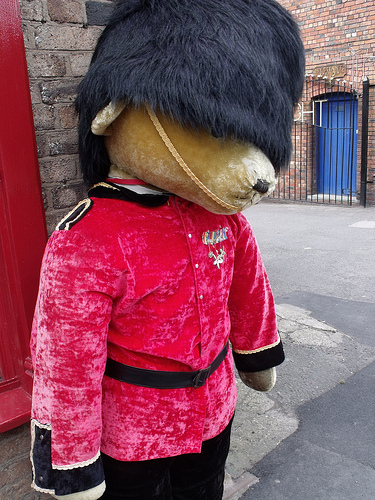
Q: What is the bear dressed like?
A: Royal guard.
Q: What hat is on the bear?
A: Tall black hat.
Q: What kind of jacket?
A: Red velvet.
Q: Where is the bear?
A: Standing on asphalt.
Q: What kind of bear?
A: Brown teddy bear.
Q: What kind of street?
A: Paved.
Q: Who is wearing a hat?
A: A stuffed animal.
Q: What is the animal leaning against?
A: A wall.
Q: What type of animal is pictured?
A: A dog.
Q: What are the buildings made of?
A: Brick.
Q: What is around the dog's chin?
A: A chin strap.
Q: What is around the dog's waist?
A: A black belt.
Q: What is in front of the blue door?
A: A fence.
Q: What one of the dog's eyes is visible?
A: Its right eye.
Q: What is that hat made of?
A: Black fur.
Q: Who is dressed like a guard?
A: A teddy bear.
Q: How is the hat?
A: Black and fuzzy.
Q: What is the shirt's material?
A: Velvet.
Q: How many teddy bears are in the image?
A: One.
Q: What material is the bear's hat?
A: Fur.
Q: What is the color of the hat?
A: Black.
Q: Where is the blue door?
A: On the right.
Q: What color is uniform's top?
A: Red.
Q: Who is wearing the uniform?
A: A teddy bear.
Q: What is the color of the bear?
A: Tan.